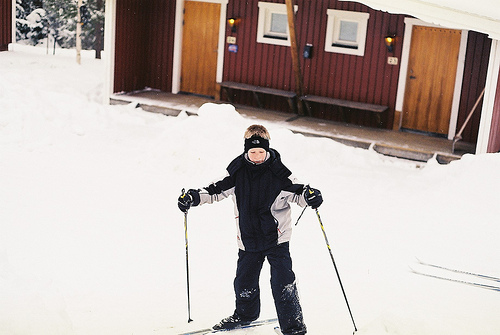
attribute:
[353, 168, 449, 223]
snow field — white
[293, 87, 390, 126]
bench — wood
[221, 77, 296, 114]
bench — wood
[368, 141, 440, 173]
stairs — not shovelled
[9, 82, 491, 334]
snow field — white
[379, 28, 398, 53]
light — on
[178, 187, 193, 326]
ski pole — upright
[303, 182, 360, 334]
ski pole — upright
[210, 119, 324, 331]
girl — little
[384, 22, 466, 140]
door — light brown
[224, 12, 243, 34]
light — on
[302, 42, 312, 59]
mailbox — empty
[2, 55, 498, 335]
snow — white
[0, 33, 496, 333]
field — white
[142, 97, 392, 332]
boy — young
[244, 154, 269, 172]
ski mask — black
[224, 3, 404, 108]
siding — red, wood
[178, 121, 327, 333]
boy — young